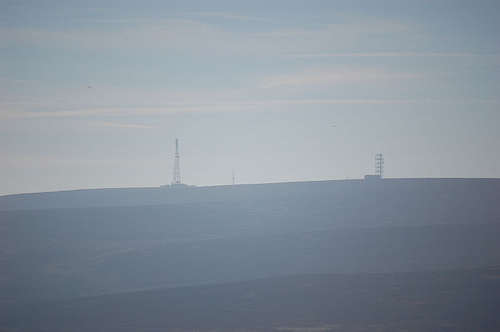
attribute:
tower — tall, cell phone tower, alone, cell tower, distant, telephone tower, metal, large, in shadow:
[171, 136, 182, 186]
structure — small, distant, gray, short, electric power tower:
[231, 165, 236, 185]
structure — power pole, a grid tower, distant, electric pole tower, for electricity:
[363, 150, 386, 178]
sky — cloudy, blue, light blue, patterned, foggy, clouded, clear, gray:
[1, 2, 499, 196]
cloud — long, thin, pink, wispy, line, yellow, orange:
[2, 97, 500, 115]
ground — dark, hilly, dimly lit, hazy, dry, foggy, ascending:
[0, 177, 500, 332]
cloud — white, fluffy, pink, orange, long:
[3, 17, 500, 49]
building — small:
[364, 173, 380, 181]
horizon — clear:
[0, 177, 500, 200]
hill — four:
[0, 226, 500, 305]